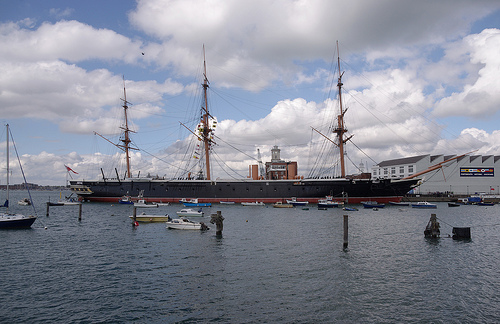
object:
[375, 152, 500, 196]
building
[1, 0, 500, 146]
background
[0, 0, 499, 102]
sky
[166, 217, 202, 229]
boat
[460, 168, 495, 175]
sign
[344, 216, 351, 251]
pole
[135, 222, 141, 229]
bowie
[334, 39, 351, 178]
mast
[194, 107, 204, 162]
flag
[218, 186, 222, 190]
window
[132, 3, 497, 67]
clouds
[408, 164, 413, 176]
window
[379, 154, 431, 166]
roof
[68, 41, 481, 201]
ship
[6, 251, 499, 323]
water